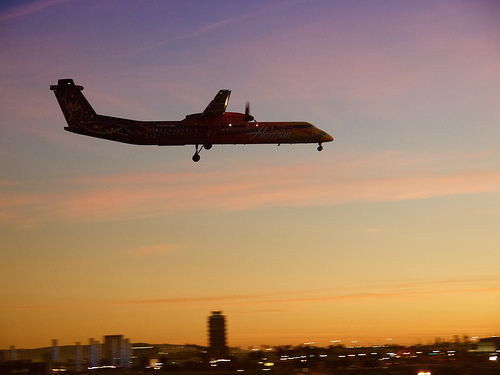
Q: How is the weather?
A: It is cloudy.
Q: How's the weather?
A: It is cloudy.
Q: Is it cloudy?
A: Yes, it is cloudy.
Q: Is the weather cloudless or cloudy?
A: It is cloudy.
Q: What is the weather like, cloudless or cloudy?
A: It is cloudy.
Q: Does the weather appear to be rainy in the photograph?
A: No, it is cloudy.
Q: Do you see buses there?
A: No, there are no buses.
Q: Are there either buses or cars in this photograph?
A: No, there are no buses or cars.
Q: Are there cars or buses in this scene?
A: No, there are no buses or cars.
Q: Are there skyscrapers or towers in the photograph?
A: Yes, there is a skyscraper.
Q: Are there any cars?
A: No, there are no cars.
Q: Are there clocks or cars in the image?
A: No, there are no cars or clocks.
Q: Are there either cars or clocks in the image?
A: No, there are no cars or clocks.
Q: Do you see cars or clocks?
A: No, there are no cars or clocks.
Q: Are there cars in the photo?
A: No, there are no cars.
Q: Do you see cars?
A: No, there are no cars.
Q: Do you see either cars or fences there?
A: No, there are no cars or fences.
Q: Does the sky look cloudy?
A: Yes, the sky is cloudy.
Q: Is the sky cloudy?
A: Yes, the sky is cloudy.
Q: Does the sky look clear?
A: No, the sky is cloudy.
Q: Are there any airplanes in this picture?
A: Yes, there is an airplane.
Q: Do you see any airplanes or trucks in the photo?
A: Yes, there is an airplane.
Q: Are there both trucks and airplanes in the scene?
A: No, there is an airplane but no trucks.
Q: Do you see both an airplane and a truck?
A: No, there is an airplane but no trucks.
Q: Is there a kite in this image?
A: No, there are no kites.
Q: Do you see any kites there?
A: No, there are no kites.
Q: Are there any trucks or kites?
A: No, there are no kites or trucks.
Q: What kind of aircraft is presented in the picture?
A: The aircraft is an airplane.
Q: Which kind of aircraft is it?
A: The aircraft is an airplane.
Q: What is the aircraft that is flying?
A: The aircraft is an airplane.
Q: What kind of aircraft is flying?
A: The aircraft is an airplane.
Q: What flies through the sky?
A: The plane flies through the sky.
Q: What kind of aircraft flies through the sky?
A: The aircraft is an airplane.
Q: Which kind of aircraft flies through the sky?
A: The aircraft is an airplane.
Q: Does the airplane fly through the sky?
A: Yes, the airplane flies through the sky.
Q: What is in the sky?
A: The plane is in the sky.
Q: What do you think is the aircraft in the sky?
A: The aircraft is an airplane.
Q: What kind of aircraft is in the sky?
A: The aircraft is an airplane.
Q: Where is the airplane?
A: The airplane is in the sky.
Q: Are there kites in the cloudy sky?
A: No, there is an airplane in the sky.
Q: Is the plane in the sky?
A: Yes, the plane is in the sky.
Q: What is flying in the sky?
A: The plane is flying in the sky.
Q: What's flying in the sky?
A: The plane is flying in the sky.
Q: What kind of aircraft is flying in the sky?
A: The aircraft is an airplane.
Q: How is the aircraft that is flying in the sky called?
A: The aircraft is an airplane.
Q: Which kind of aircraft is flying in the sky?
A: The aircraft is an airplane.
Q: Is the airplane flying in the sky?
A: Yes, the airplane is flying in the sky.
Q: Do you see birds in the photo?
A: No, there are no birds.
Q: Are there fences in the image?
A: No, there are no fences.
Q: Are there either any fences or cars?
A: No, there are no fences or cars.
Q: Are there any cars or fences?
A: No, there are no fences or cars.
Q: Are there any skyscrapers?
A: Yes, there is a skyscraper.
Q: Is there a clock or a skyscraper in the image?
A: Yes, there is a skyscraper.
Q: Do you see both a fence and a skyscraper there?
A: No, there is a skyscraper but no fences.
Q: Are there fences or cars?
A: No, there are no cars or fences.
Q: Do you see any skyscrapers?
A: Yes, there is a skyscraper.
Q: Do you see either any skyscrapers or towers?
A: Yes, there is a skyscraper.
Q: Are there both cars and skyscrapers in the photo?
A: No, there is a skyscraper but no cars.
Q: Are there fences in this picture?
A: No, there are no fences.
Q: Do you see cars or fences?
A: No, there are no fences or cars.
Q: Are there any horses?
A: No, there are no horses.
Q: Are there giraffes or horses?
A: No, there are no horses or giraffes.